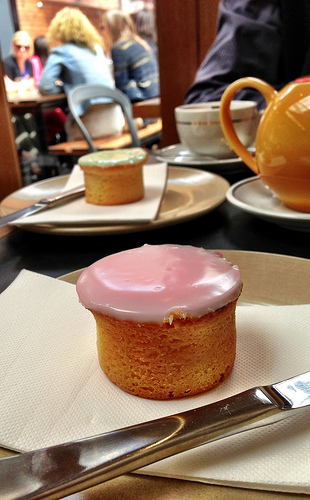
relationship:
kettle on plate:
[216, 66, 309, 224] [9, 125, 244, 241]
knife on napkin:
[9, 364, 301, 492] [13, 275, 308, 487]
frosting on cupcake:
[78, 147, 148, 168] [77, 147, 148, 205]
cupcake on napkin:
[77, 147, 148, 205] [6, 188, 167, 224]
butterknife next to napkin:
[0, 183, 85, 228] [12, 255, 293, 415]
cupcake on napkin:
[77, 147, 148, 205] [7, 174, 169, 226]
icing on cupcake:
[63, 235, 253, 320] [60, 236, 251, 405]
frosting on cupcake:
[78, 147, 148, 168] [61, 136, 171, 214]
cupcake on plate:
[74, 147, 149, 205] [1, 162, 232, 238]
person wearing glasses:
[37, 3, 110, 118] [11, 38, 36, 56]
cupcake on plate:
[74, 147, 149, 205] [0, 156, 233, 242]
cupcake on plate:
[75, 242, 244, 401] [0, 244, 309, 497]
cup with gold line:
[174, 99, 264, 159] [174, 116, 258, 125]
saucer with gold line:
[130, 113, 280, 184] [173, 115, 260, 123]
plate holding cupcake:
[0, 163, 230, 233] [74, 147, 149, 205]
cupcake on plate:
[75, 242, 244, 401] [249, 240, 307, 297]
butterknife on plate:
[9, 186, 90, 222] [5, 174, 228, 232]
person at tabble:
[161, 12, 301, 81] [31, 112, 308, 414]